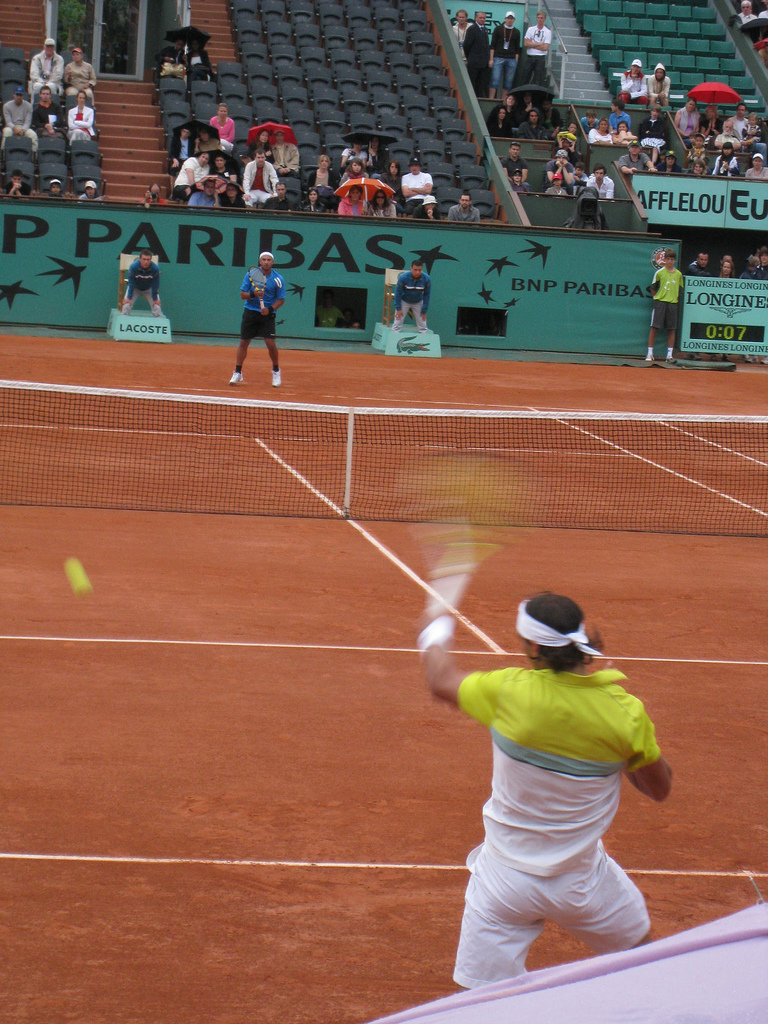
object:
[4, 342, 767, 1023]
tennis court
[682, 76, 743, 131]
umbrella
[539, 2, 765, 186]
stands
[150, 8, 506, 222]
stands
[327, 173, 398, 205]
umbrella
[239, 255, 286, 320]
shirt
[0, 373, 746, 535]
tennis net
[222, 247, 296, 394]
player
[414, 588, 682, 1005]
player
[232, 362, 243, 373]
sock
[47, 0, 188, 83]
door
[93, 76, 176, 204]
stairs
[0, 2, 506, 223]
stands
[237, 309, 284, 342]
shorts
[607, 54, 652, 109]
person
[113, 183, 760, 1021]
tennis match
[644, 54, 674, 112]
person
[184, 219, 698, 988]
tennis match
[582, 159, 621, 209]
person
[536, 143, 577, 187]
person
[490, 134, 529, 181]
person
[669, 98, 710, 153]
person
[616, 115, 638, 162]
person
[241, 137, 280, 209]
person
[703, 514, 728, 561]
bad sentence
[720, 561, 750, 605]
bad sentence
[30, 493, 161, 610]
air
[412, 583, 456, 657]
hand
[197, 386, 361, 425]
edge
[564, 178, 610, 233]
camera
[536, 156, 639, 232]
stands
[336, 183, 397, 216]
spectators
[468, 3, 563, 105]
people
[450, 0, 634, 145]
stands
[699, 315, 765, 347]
numbers